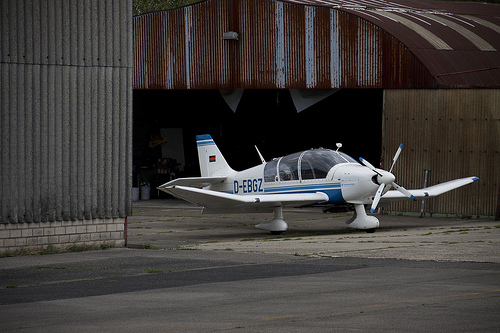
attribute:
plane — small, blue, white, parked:
[156, 126, 488, 224]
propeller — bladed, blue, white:
[366, 143, 415, 208]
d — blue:
[231, 177, 244, 194]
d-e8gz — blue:
[228, 170, 266, 198]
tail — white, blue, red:
[194, 130, 230, 177]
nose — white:
[381, 167, 397, 187]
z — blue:
[259, 177, 265, 193]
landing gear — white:
[247, 205, 381, 241]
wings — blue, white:
[166, 164, 484, 209]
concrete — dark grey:
[2, 193, 492, 333]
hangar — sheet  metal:
[2, 4, 499, 232]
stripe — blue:
[257, 180, 348, 198]